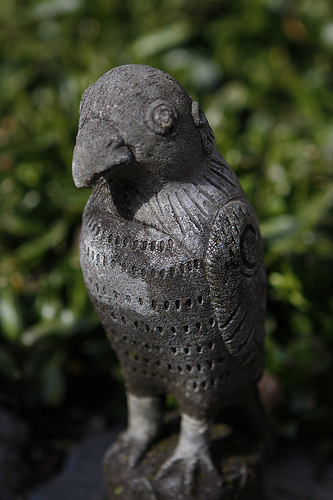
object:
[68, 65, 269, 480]
statue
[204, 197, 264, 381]
wing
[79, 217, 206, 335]
breast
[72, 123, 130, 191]
beak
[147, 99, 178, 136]
eye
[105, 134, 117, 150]
nostril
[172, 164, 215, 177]
neck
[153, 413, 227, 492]
foot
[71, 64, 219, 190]
head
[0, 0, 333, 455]
leaves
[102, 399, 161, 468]
foot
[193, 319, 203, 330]
hole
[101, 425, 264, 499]
pedestool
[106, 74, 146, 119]
stone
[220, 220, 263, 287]
etching